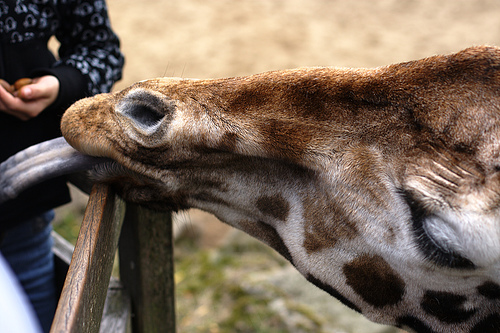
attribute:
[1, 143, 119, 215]
tongue — black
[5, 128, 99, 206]
tongue — black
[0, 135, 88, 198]
tongue — black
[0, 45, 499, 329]
giraffe — brown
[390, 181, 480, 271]
eye — closed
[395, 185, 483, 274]
eye — closed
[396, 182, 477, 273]
eye — closed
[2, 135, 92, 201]
tongue — gray, long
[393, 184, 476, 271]
lashes — black, long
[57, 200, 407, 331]
grass — green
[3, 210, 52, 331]
jeans — blue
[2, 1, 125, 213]
sweater — blue, floral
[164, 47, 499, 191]
forehead — brown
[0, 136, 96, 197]
tongue — out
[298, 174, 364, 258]
spot — brown, big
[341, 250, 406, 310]
spot — big, brown, large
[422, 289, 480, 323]
spot — big, brown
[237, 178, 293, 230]
spot — brown, big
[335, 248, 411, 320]
spot — brown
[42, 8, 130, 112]
sleeve — black, white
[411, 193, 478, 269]
eyeball — closed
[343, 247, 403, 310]
spot — brown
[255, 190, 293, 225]
spot — brown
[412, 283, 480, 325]
spot — brown